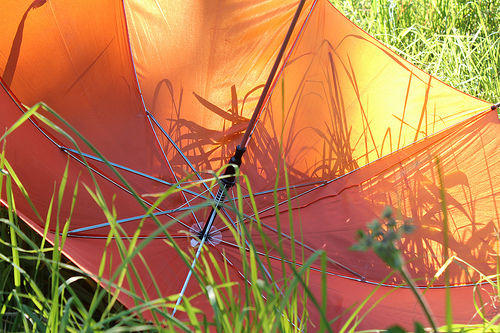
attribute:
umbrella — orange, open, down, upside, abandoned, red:
[48, 26, 475, 264]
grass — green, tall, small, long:
[391, 11, 497, 85]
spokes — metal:
[148, 129, 326, 245]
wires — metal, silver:
[65, 126, 371, 280]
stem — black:
[225, 143, 247, 187]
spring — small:
[217, 186, 226, 205]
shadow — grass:
[211, 43, 422, 164]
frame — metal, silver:
[117, 17, 229, 219]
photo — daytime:
[27, 18, 495, 330]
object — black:
[225, 138, 242, 198]